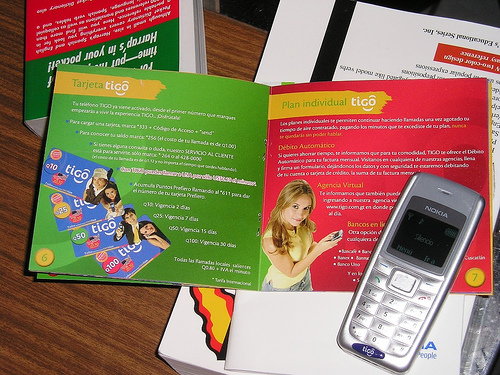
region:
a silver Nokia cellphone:
[337, 172, 485, 373]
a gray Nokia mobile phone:
[334, 171, 487, 373]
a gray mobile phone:
[334, 170, 485, 372]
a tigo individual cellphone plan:
[27, 62, 492, 295]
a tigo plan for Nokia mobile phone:
[25, 63, 492, 373]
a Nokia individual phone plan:
[27, 63, 491, 293]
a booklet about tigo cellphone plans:
[26, 62, 492, 292]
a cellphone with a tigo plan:
[335, 172, 486, 374]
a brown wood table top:
[2, 285, 155, 372]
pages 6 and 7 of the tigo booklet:
[24, 63, 491, 294]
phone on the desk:
[370, 168, 441, 368]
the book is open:
[41, 70, 495, 292]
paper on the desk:
[127, 283, 314, 369]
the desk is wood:
[25, 312, 130, 367]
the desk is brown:
[25, 312, 129, 346]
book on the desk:
[300, 20, 493, 72]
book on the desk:
[42, 31, 173, 113]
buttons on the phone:
[351, 272, 413, 355]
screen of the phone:
[390, 206, 447, 267]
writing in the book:
[130, 181, 225, 251]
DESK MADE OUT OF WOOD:
[93, 309, 145, 362]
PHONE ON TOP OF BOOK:
[351, 184, 479, 370]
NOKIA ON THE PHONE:
[421, 197, 453, 227]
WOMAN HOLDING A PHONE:
[326, 227, 343, 247]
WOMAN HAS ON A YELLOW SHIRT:
[298, 235, 306, 242]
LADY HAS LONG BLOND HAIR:
[281, 187, 292, 204]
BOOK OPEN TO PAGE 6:
[31, 247, 58, 270]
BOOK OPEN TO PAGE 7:
[462, 270, 487, 287]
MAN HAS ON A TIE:
[133, 230, 138, 240]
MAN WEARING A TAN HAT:
[94, 167, 109, 177]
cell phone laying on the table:
[313, 170, 490, 372]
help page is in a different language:
[59, 64, 262, 277]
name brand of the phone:
[416, 197, 456, 224]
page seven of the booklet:
[461, 261, 488, 295]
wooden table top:
[8, 301, 95, 367]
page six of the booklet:
[31, 235, 57, 275]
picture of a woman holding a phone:
[268, 190, 347, 290]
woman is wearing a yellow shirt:
[265, 228, 315, 280]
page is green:
[223, 90, 264, 149]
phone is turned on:
[390, 206, 456, 282]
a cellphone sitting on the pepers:
[336, 165, 491, 373]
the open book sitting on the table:
[31, 60, 493, 297]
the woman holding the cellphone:
[263, 180, 343, 292]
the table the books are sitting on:
[6, 2, 274, 374]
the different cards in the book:
[38, 148, 168, 278]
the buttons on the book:
[350, 260, 436, 361]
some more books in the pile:
[151, 288, 472, 373]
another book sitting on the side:
[21, 0, 208, 135]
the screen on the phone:
[389, 213, 460, 266]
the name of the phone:
[348, 93, 378, 115]